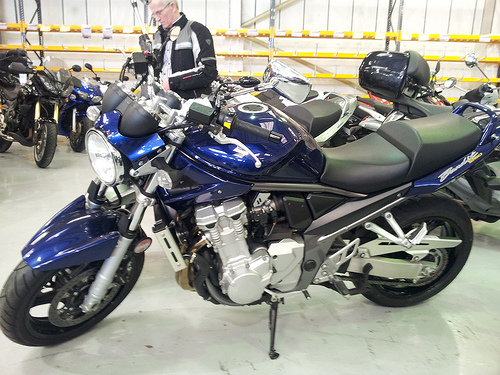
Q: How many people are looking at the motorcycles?
A: 1.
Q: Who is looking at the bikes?
A: The man.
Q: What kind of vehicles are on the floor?
A: Motorcycles.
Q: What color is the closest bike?
A: Blue.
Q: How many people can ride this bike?
A: 2.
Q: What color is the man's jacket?
A: Black.